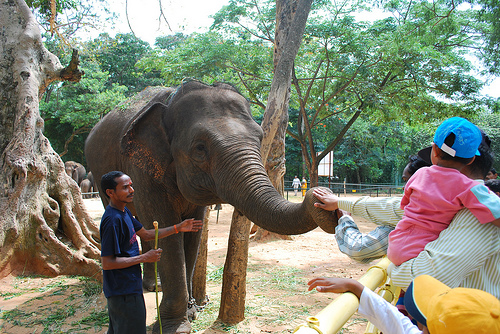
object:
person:
[312, 125, 500, 295]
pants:
[105, 294, 146, 333]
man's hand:
[306, 277, 353, 292]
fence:
[288, 253, 395, 334]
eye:
[196, 144, 206, 151]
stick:
[149, 218, 161, 333]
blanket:
[305, 185, 339, 234]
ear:
[430, 142, 439, 157]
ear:
[467, 155, 476, 165]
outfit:
[386, 164, 499, 266]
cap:
[402, 274, 500, 331]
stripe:
[407, 280, 426, 322]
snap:
[440, 143, 456, 158]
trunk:
[208, 132, 341, 236]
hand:
[312, 187, 336, 212]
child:
[307, 276, 500, 331]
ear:
[118, 102, 172, 186]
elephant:
[82, 78, 340, 333]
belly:
[84, 96, 135, 217]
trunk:
[214, 145, 338, 234]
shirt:
[337, 178, 500, 302]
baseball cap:
[432, 117, 481, 158]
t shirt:
[98, 205, 144, 299]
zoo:
[0, 0, 500, 332]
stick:
[153, 221, 163, 333]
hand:
[144, 248, 163, 263]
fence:
[77, 177, 405, 197]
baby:
[386, 117, 498, 265]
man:
[98, 169, 202, 334]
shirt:
[354, 286, 421, 334]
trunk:
[220, 151, 334, 245]